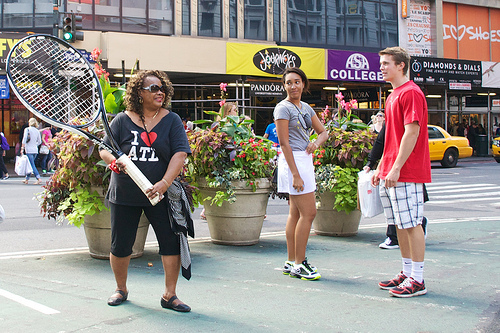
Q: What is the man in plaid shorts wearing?
A: A red shirt.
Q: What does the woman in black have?
A: A large racket.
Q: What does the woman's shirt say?
A: I heart ATL.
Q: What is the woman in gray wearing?
A: A white skirt.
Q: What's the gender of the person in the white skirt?
A: Female.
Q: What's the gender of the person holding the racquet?
A: Female.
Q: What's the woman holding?
A: Huge racquet.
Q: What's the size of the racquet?
A: Large.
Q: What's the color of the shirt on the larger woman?
A: Black.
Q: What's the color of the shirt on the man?
A: Red.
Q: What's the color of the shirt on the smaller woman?
A: Grey.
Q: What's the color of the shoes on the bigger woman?
A: Black.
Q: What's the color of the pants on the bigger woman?
A: Black.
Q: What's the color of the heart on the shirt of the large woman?
A: Red.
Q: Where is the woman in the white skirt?
A: In the middle.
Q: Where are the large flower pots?
A: Behind people.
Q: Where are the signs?
A: On buildings.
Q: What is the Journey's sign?
A: Yellow with black circle white writing.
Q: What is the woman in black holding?
A: Tennis racket.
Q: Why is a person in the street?
A: Shopping.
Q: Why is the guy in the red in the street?
A: Shopping.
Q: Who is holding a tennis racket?
A: Woman in black.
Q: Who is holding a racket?
A: Woman in black.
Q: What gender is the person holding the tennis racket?
A: Female.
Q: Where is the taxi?
A: In front of the building.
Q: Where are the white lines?
A: Road.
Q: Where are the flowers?
A: Flower pots.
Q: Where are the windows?
A: Buildings.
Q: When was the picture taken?
A: Daytime.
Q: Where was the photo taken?
A: Near a city street.